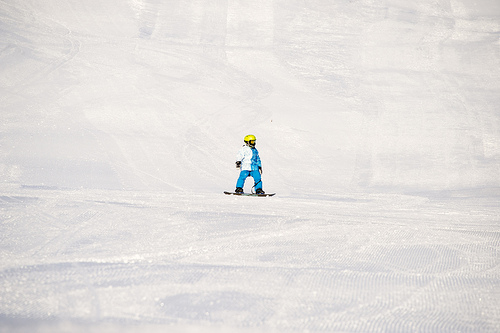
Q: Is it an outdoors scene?
A: Yes, it is outdoors.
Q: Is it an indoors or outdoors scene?
A: It is outdoors.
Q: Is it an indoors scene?
A: No, it is outdoors.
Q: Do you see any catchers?
A: No, there are no catchers.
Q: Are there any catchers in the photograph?
A: No, there are no catchers.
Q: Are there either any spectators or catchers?
A: No, there are no catchers or spectators.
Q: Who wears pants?
A: The man wears pants.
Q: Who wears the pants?
A: The man wears pants.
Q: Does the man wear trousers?
A: Yes, the man wears trousers.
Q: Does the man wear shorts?
A: No, the man wears trousers.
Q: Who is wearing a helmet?
A: The man is wearing a helmet.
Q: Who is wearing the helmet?
A: The man is wearing a helmet.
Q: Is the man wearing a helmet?
A: Yes, the man is wearing a helmet.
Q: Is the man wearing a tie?
A: No, the man is wearing a helmet.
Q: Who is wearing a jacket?
A: The man is wearing a jacket.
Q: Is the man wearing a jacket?
A: Yes, the man is wearing a jacket.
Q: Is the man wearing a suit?
A: No, the man is wearing a jacket.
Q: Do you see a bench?
A: No, there are no benches.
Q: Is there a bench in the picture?
A: No, there are no benches.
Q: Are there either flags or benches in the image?
A: No, there are no benches or flags.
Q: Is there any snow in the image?
A: Yes, there is snow.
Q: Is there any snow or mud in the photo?
A: Yes, there is snow.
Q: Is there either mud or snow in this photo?
A: Yes, there is snow.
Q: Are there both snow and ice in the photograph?
A: No, there is snow but no ice.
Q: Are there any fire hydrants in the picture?
A: No, there are no fire hydrants.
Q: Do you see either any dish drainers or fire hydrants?
A: No, there are no fire hydrants or dish drainers.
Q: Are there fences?
A: No, there are no fences.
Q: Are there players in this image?
A: No, there are no players.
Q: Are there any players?
A: No, there are no players.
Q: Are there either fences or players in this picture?
A: No, there are no players or fences.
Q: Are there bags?
A: No, there are no bags.